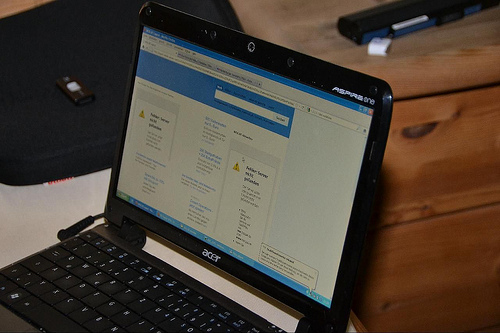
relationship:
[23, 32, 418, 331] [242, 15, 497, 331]
laptop in front of drawers